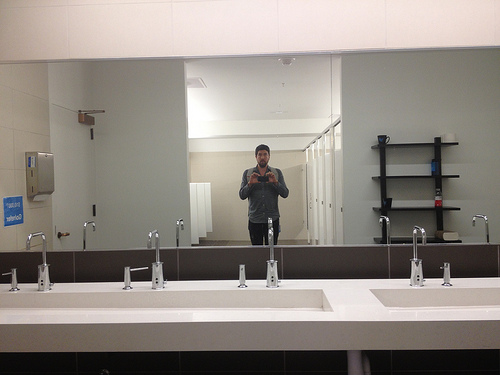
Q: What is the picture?
A: Restroom.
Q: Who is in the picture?
A: Guy.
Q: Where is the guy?
A: By the stalls.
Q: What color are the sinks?
A: White.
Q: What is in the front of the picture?
A: Sinks.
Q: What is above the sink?
A: Mirror.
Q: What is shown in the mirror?
A: Shelf.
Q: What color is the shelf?
A: Black.